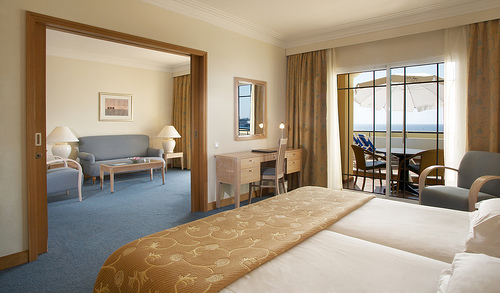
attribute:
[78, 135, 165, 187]
sofa —  light blue,   seat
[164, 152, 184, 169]
table — end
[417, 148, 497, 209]
chair — blue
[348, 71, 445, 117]
umbrella — white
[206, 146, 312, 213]
desk —  small,   five drawered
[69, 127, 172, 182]
couch — blue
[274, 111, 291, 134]
lightbulb —  lit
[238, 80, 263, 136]
mirror —  wooden trimmed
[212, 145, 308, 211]
desk — wooden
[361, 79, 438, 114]
patio umbrella —  white,  at patio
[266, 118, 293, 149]
lamp — small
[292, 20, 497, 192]
curtains —  Large,  luxurious,  tan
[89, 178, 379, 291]
blanket — yellow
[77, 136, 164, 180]
sofa — blue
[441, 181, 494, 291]
pillows — white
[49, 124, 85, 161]
lamp — large, white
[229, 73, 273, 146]
frame — wooden